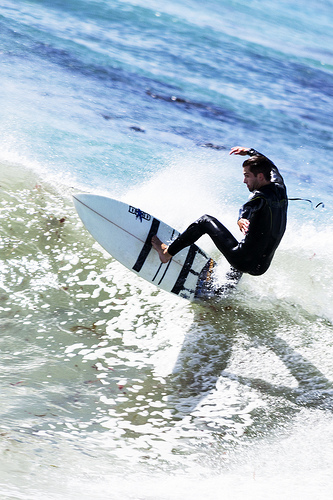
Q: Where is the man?
A: On the ocean.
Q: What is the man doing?
A: Surfing.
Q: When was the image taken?
A: Daytime.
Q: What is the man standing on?
A: A surfboard.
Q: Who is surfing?
A: The man.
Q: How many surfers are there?
A: 1.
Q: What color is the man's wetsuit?
A: Black.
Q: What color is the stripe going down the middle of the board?
A: Red.